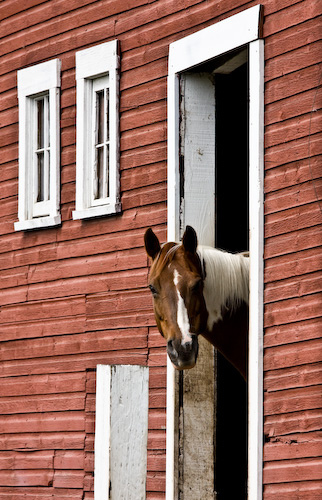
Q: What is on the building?
A: Windows.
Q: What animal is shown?
A: Horse.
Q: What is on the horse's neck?
A: Mane.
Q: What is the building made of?
A: Wood.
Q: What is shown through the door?
A: The head of the horse.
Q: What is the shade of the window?
A: White.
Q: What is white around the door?
A: Trim.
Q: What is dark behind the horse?
A: Through the door.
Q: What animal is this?
A: A horse.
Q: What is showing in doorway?
A: Horse's head.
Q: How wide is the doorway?
A: Narrow.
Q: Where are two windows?
A: To left of door.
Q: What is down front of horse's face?
A: White stripe.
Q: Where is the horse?
A: Doorway.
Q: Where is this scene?
A: Barn.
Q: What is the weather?
A: Fair.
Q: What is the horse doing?
A: Looking.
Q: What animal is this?
A: A horse.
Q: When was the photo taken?
A: Daytime.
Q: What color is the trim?
A: White.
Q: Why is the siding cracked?
A: It is old.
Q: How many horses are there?
A: One.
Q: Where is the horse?
A: In the barn.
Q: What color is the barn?
A: Red.